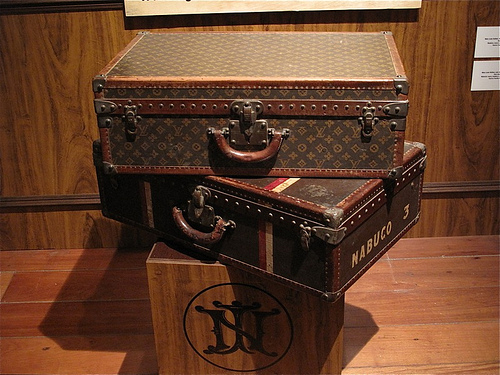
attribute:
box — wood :
[144, 242, 346, 374]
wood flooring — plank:
[1, 231, 497, 372]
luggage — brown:
[92, 135, 426, 302]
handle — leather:
[211, 130, 283, 162]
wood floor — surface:
[375, 242, 480, 372]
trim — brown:
[100, 156, 405, 185]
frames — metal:
[389, 80, 410, 119]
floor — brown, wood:
[20, 242, 497, 371]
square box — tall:
[147, 255, 357, 372]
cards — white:
[461, 5, 496, 107]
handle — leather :
[199, 121, 294, 168]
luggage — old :
[83, 22, 415, 190]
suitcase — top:
[137, 32, 377, 132]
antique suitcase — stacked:
[89, 32, 410, 188]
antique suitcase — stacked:
[85, 138, 426, 301]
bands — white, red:
[247, 217, 290, 292]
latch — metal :
[98, 97, 168, 139]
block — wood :
[146, 238, 343, 373]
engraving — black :
[177, 280, 296, 372]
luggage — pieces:
[98, 132, 444, 306]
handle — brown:
[188, 113, 302, 173]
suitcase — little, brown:
[85, 21, 425, 189]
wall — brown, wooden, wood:
[7, 10, 498, 239]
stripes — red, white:
[246, 170, 315, 280]